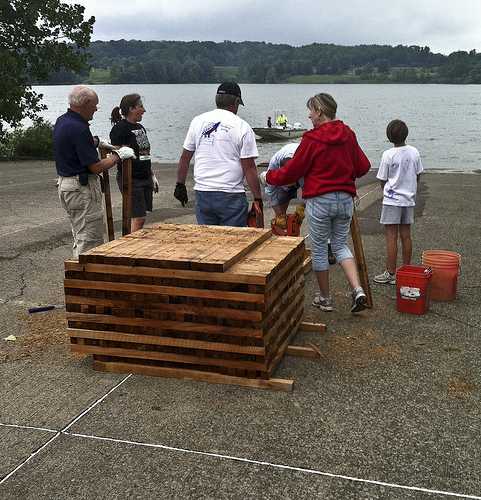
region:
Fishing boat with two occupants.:
[245, 111, 310, 141]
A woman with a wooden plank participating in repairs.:
[257, 89, 378, 315]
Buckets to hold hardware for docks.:
[390, 246, 462, 318]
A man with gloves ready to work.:
[47, 81, 137, 262]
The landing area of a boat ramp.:
[4, 154, 478, 498]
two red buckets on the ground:
[390, 247, 464, 316]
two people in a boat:
[250, 107, 308, 142]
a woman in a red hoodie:
[258, 91, 373, 313]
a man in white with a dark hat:
[171, 79, 266, 227]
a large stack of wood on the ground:
[61, 223, 313, 385]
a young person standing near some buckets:
[371, 118, 425, 264]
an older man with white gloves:
[51, 84, 137, 246]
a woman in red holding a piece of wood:
[260, 93, 374, 315]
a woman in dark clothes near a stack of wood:
[106, 93, 162, 226]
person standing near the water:
[371, 117, 427, 285]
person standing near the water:
[255, 89, 376, 315]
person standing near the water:
[166, 81, 267, 222]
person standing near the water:
[103, 90, 162, 228]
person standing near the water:
[50, 83, 139, 257]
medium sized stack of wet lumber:
[53, 213, 336, 395]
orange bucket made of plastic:
[421, 248, 462, 302]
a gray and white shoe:
[344, 284, 371, 316]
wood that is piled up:
[65, 178, 412, 448]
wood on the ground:
[77, 188, 341, 444]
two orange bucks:
[407, 228, 473, 331]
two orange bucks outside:
[391, 235, 459, 325]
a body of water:
[344, 92, 480, 153]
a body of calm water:
[369, 90, 480, 178]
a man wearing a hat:
[173, 84, 258, 235]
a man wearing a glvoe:
[168, 174, 189, 203]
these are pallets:
[120, 243, 311, 451]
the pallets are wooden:
[94, 209, 386, 454]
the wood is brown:
[120, 261, 254, 377]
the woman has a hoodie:
[265, 104, 370, 223]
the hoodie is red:
[307, 100, 392, 209]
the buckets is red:
[388, 277, 437, 307]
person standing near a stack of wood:
[371, 113, 424, 289]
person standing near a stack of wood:
[253, 88, 376, 318]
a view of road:
[85, 404, 214, 485]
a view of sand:
[219, 412, 280, 442]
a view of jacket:
[275, 133, 376, 191]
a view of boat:
[229, 99, 355, 167]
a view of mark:
[192, 115, 237, 154]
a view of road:
[205, 424, 277, 478]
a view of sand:
[287, 481, 330, 496]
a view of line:
[168, 428, 235, 467]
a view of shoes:
[329, 281, 410, 337]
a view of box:
[363, 241, 438, 337]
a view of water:
[324, 47, 444, 141]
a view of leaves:
[47, 12, 110, 70]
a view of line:
[244, 459, 275, 474]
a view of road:
[193, 447, 300, 495]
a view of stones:
[279, 413, 360, 467]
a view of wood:
[99, 209, 321, 381]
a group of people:
[28, 70, 443, 307]